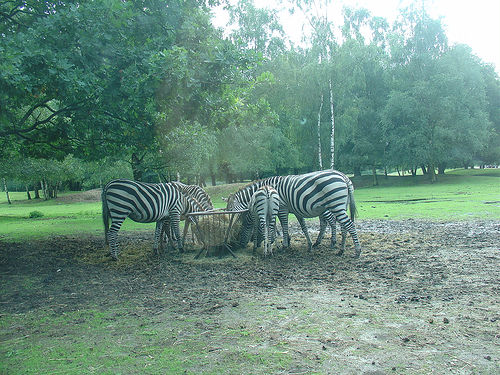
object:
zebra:
[101, 179, 206, 262]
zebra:
[224, 186, 279, 259]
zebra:
[222, 169, 362, 259]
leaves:
[0, 1, 240, 164]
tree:
[0, 2, 252, 168]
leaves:
[383, 42, 499, 165]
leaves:
[200, 32, 289, 182]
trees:
[2, 171, 63, 207]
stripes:
[137, 185, 162, 215]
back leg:
[336, 223, 348, 257]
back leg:
[336, 214, 362, 259]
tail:
[101, 190, 111, 245]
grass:
[2, 170, 500, 374]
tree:
[371, 45, 497, 185]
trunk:
[428, 164, 437, 185]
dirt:
[4, 219, 499, 342]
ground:
[2, 168, 499, 375]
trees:
[162, 2, 499, 182]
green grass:
[2, 167, 497, 236]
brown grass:
[0, 217, 500, 375]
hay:
[185, 208, 249, 260]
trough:
[187, 208, 252, 260]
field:
[3, 168, 499, 237]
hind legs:
[108, 216, 127, 262]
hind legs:
[258, 210, 266, 260]